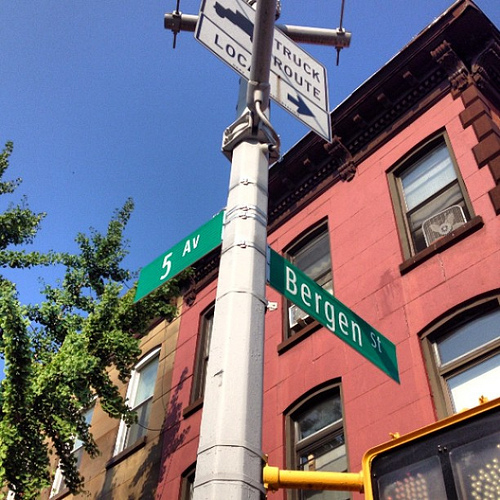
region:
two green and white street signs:
[113, 228, 416, 380]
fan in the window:
[409, 190, 491, 257]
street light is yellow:
[302, 442, 487, 486]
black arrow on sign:
[281, 87, 335, 125]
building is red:
[322, 193, 398, 303]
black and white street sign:
[199, 14, 364, 127]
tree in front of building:
[48, 227, 106, 463]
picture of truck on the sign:
[214, 4, 262, 46]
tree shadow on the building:
[67, 382, 222, 498]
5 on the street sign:
[130, 238, 187, 287]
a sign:
[96, 201, 231, 463]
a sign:
[212, 216, 352, 365]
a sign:
[257, 260, 346, 425]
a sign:
[238, 237, 393, 496]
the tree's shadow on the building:
[133, 362, 189, 498]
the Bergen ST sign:
[265, 243, 400, 382]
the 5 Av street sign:
[129, 223, 218, 293]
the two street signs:
[137, 212, 402, 390]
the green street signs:
[132, 214, 402, 384]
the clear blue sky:
[31, 64, 201, 191]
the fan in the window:
[420, 206, 469, 241]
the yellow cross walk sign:
[261, 387, 496, 497]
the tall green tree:
[2, 141, 165, 498]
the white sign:
[191, 0, 337, 139]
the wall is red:
[338, 386, 432, 460]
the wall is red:
[348, 377, 472, 437]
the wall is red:
[388, 362, 477, 419]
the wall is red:
[347, 343, 434, 421]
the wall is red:
[335, 310, 430, 451]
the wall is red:
[371, 370, 420, 445]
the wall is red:
[377, 369, 455, 477]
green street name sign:
[265, 245, 402, 385]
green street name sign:
[130, 206, 218, 288]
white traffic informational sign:
[194, 1, 336, 143]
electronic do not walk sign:
[254, 391, 496, 496]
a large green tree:
[6, 139, 165, 496]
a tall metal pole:
[192, 62, 282, 498]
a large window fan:
[419, 209, 467, 246]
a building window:
[382, 137, 479, 267]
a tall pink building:
[143, 14, 498, 487]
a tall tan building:
[6, 263, 188, 498]